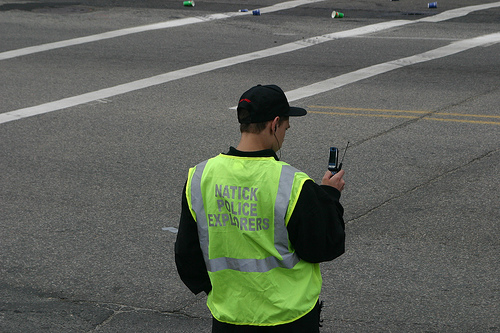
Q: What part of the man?
A: Back.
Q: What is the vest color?
A: Yellow.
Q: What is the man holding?
A: Phone.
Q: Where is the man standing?
A: Street.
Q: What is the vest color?
A: Yellow.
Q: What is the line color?
A: White.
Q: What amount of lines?
A: Two.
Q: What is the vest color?
A: Green.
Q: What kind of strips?
A: Reflective.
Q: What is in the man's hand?
A: A phone.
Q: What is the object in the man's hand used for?
A: Making calls.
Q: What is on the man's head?
A: A hat.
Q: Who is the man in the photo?
A: A policeman.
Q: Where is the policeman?
A: In the street.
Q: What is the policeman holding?
A: A radio.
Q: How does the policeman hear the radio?
A: Through his earphone.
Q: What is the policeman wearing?
A: A vest.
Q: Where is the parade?
A: It's over.